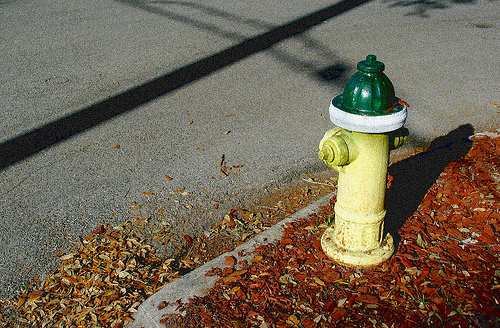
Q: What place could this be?
A: It is a pavement.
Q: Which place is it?
A: It is a pavement.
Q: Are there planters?
A: No, there are no planters.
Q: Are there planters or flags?
A: No, there are no planters or flags.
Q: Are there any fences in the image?
A: No, there are no fences.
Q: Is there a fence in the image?
A: No, there are no fences.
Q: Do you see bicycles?
A: No, there are no bicycles.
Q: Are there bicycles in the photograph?
A: No, there are no bicycles.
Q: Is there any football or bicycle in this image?
A: No, there are no bicycles or footballs.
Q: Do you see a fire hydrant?
A: Yes, there is a fire hydrant.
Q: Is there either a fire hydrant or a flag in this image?
A: Yes, there is a fire hydrant.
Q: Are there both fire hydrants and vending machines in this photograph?
A: No, there is a fire hydrant but no vending machines.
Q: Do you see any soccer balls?
A: No, there are no soccer balls.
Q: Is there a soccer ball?
A: No, there are no soccer balls.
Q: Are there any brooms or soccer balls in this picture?
A: No, there are no soccer balls or brooms.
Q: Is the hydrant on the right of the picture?
A: Yes, the hydrant is on the right of the image.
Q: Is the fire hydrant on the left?
A: No, the fire hydrant is on the right of the image.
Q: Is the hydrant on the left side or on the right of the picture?
A: The hydrant is on the right of the image.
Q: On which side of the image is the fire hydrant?
A: The fire hydrant is on the right of the image.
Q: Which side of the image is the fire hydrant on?
A: The fire hydrant is on the right of the image.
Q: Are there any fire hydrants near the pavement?
A: Yes, there is a fire hydrant near the pavement.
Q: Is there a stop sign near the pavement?
A: No, there is a fire hydrant near the pavement.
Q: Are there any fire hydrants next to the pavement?
A: Yes, there is a fire hydrant next to the pavement.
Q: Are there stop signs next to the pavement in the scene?
A: No, there is a fire hydrant next to the pavement.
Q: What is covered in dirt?
A: The hydrant is covered in dirt.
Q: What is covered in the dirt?
A: The hydrant is covered in dirt.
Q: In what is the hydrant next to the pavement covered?
A: The hydrant is covered in dirt.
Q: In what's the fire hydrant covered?
A: The hydrant is covered in dirt.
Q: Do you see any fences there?
A: No, there are no fences.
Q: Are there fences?
A: No, there are no fences.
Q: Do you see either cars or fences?
A: No, there are no fences or cars.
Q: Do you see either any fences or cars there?
A: No, there are no fences or cars.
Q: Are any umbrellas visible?
A: No, there are no umbrellas.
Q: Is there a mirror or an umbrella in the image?
A: No, there are no umbrellas or mirrors.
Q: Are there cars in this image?
A: No, there are no cars.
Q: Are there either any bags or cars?
A: No, there are no cars or bags.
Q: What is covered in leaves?
A: The sidewalk is covered in leaves.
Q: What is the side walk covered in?
A: The side walk is covered in leaves.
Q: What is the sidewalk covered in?
A: The side walk is covered in leaves.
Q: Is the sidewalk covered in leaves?
A: Yes, the sidewalk is covered in leaves.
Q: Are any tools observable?
A: No, there are no tools.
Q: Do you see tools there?
A: No, there are no tools.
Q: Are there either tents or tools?
A: No, there are no tools or tents.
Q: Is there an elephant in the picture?
A: No, there are no elephants.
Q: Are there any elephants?
A: No, there are no elephants.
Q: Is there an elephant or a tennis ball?
A: No, there are no elephants or tennis balls.